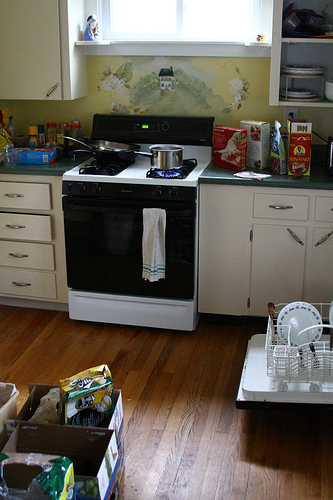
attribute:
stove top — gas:
[65, 145, 208, 187]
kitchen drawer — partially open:
[0, 201, 58, 246]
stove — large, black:
[68, 98, 199, 294]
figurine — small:
[79, 13, 100, 42]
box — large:
[286, 118, 311, 176]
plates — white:
[276, 302, 322, 348]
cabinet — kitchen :
[267, 2, 331, 106]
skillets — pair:
[63, 135, 146, 165]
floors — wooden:
[0, 304, 332, 496]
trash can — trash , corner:
[0, 380, 21, 439]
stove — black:
[55, 102, 218, 338]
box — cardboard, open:
[7, 379, 125, 461]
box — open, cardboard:
[3, 418, 121, 498]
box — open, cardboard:
[1, 450, 78, 498]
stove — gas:
[60, 113, 215, 330]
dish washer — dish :
[230, 294, 332, 414]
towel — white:
[139, 205, 168, 283]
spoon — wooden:
[266, 300, 276, 332]